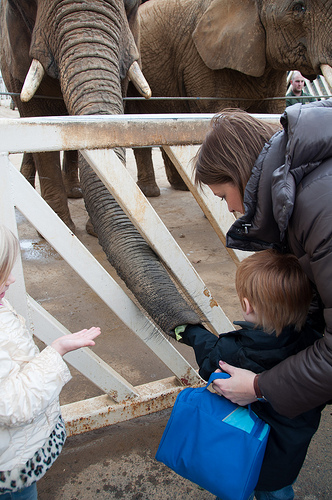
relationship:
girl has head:
[0, 226, 97, 498] [0, 221, 26, 306]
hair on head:
[0, 227, 14, 286] [0, 221, 26, 306]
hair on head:
[188, 107, 281, 216] [194, 104, 277, 215]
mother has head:
[191, 105, 332, 406] [194, 104, 277, 215]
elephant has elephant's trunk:
[0, 0, 213, 344] [41, 9, 203, 339]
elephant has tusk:
[0, 0, 206, 335] [18, 58, 51, 100]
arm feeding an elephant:
[173, 254, 327, 499] [0, 0, 331, 343]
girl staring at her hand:
[0, 226, 97, 498] [45, 317, 106, 356]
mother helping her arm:
[197, 106, 329, 265] [173, 254, 327, 499]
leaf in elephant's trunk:
[173, 322, 190, 343] [46, 11, 203, 339]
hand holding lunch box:
[211, 353, 266, 407] [151, 368, 272, 498]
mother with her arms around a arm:
[191, 105, 332, 406] [173, 254, 327, 499]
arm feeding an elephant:
[173, 254, 327, 499] [0, 0, 213, 344]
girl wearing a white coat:
[0, 226, 97, 498] [0, 297, 68, 494]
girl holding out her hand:
[0, 226, 97, 498] [47, 323, 102, 355]